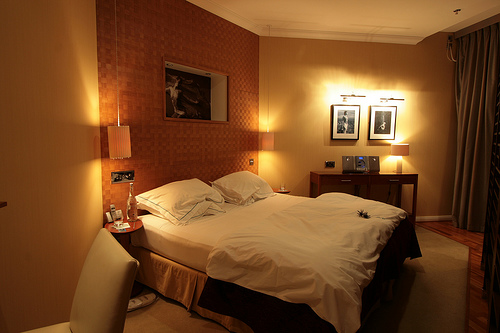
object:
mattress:
[126, 184, 409, 302]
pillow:
[212, 170, 276, 204]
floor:
[400, 249, 468, 332]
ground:
[0, 292, 254, 333]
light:
[389, 142, 414, 174]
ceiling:
[179, 0, 500, 47]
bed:
[130, 170, 423, 332]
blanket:
[202, 191, 422, 333]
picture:
[332, 104, 360, 140]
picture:
[370, 105, 395, 140]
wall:
[255, 29, 457, 221]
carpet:
[382, 273, 459, 332]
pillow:
[130, 175, 226, 226]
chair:
[16, 232, 140, 333]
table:
[103, 217, 145, 316]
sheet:
[202, 192, 407, 333]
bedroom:
[0, 0, 500, 333]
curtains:
[444, 26, 500, 237]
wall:
[0, 0, 260, 333]